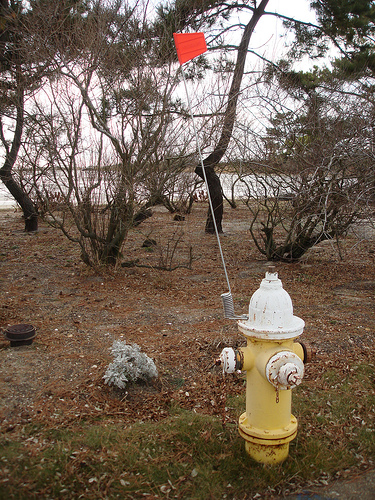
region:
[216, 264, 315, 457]
yellow and white fire hydrant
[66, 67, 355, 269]
trees with few leaves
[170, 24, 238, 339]
red flag attached to fire hydrant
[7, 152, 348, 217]
lake behind trees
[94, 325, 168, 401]
small light green plant near fire hydrant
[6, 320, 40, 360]
brown metal pipe in ground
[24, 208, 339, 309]
land filled with dirt, leaves and pine needles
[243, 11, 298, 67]
clear bright sky peeping through trees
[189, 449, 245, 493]
green grass surrounding fire hydrant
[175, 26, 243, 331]
silver metal pole holding plastic red flag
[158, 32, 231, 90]
Red flag on the pole.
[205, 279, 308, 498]
Yellow hydrant on the ground.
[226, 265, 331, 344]
White top of the hydrant.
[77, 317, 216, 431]
White bush on the ground.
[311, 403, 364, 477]
Leaves on the ground.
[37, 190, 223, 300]
Brown bush on the ground.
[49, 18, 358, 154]
Sky behind the trees.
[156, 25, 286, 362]
Flag on the fire hydrant.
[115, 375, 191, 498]
Green grass on the ground.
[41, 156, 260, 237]
Water behind the trees.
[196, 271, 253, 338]
metal coil attached to a hydrant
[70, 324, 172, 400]
white foliage on the ground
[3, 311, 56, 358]
dark brown pipe protruding from the ground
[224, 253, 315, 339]
white top on the fire hydrant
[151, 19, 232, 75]
orange flag on the end of the metal rod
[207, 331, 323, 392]
white caps on a yellow hydrant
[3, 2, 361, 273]
trees behind the fire hydrant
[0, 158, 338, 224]
body of water behind the trees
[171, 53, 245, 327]
metal rod with a coil on the bottom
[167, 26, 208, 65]
small red flag flying in sky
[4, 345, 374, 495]
green grassy patch with fire hydrant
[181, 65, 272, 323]
silver metal pole attached to fire hydrant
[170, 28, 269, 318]
silver metal pole with red flag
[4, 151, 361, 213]
clear gray water in background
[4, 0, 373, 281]
slightly bare brown wooden trees in background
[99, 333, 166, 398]
small white bush next to hydrant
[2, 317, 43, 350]
brown metal plug in ground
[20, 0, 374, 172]
clear white daytime sky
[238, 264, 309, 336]
white top of fire hydrant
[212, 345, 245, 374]
water adaptor on left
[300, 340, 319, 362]
water adapter on right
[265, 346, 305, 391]
water adaptor on front of hydrant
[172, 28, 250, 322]
red flag on a metal pole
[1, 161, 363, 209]
body of water beyond the trees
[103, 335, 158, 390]
small white plant on left of picture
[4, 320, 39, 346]
brown metal cap on middle left of picture